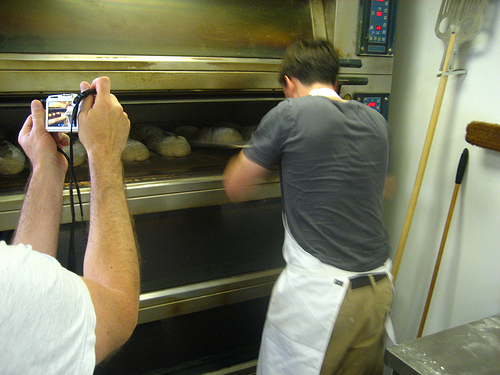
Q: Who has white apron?
A: Man in front of oven.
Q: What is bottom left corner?
A: Person with camera.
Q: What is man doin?
A: Baking bread.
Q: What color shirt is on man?
A: Gray.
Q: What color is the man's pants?
A: Tan.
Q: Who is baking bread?
A: The man.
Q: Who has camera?
A: Man taking pictures.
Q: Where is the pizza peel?
A: Against the wall.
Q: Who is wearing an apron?
A: Man near the oven.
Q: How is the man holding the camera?
A: Both hands.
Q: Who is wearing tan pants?
A: Man near the oven.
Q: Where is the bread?
A: In the oven.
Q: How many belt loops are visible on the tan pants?
A: One.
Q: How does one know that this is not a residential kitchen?
A: Commercial oven.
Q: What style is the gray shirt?
A: T-shirt.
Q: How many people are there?
A: 2.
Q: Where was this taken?
A: In a kitchen.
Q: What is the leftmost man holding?
A: A camera.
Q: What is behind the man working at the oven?
A: A metal table.